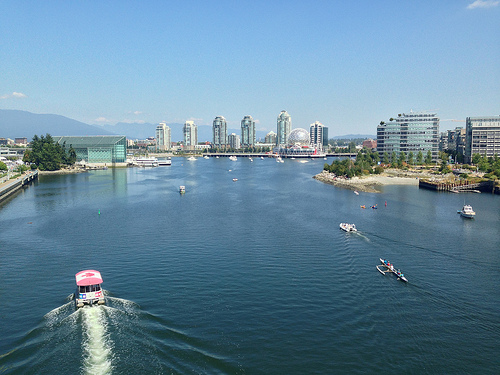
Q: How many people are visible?
A: Zero.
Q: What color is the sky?
A: Blue.